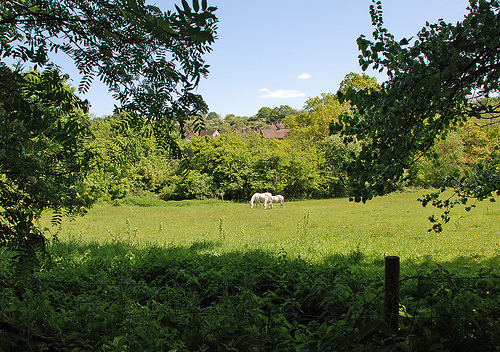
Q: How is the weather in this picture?
A: It is clear.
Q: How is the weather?
A: It is clear.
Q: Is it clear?
A: Yes, it is clear.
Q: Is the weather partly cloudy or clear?
A: It is clear.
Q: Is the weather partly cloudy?
A: No, it is clear.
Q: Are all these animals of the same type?
A: Yes, all the animals are horses.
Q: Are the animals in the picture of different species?
A: No, all the animals are horses.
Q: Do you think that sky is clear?
A: Yes, the sky is clear.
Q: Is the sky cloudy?
A: No, the sky is clear.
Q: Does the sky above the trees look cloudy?
A: No, the sky is clear.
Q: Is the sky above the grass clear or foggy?
A: The sky is clear.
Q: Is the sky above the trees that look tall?
A: Yes, the sky is above the trees.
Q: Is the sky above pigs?
A: No, the sky is above the horses.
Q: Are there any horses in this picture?
A: Yes, there is a horse.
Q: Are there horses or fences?
A: Yes, there is a horse.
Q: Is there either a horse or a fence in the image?
A: Yes, there is a horse.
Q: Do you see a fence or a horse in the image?
A: Yes, there is a horse.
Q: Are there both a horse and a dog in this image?
A: No, there is a horse but no dogs.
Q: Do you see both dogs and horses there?
A: No, there is a horse but no dogs.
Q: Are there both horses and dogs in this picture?
A: No, there is a horse but no dogs.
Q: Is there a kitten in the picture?
A: No, there are no kittens.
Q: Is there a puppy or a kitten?
A: No, there are no kittens or puppys.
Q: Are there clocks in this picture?
A: No, there are no clocks.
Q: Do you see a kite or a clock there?
A: No, there are no clocks or kites.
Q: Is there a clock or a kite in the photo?
A: No, there are no clocks or kites.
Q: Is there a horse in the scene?
A: Yes, there are horses.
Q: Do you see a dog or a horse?
A: Yes, there are horses.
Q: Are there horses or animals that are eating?
A: Yes, the horses are eating.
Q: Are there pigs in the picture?
A: No, there are no pigs.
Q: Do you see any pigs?
A: No, there are no pigs.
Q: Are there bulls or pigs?
A: No, there are no pigs or bulls.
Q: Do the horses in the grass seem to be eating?
A: Yes, the horses are eating.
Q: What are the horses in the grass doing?
A: The horses are eating.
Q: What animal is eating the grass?
A: The horses are eating the grass.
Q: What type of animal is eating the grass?
A: The animals are horses.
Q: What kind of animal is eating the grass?
A: The animals are horses.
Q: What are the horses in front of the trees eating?
A: The horses are eating grass.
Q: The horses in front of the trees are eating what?
A: The horses are eating grass.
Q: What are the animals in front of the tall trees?
A: The animals are horses.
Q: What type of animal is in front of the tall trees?
A: The animals are horses.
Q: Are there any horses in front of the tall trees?
A: Yes, there are horses in front of the trees.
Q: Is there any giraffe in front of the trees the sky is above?
A: No, there are horses in front of the trees.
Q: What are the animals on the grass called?
A: The animals are horses.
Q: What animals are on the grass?
A: The animals are horses.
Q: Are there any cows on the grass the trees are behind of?
A: No, there are horses on the grass.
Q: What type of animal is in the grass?
A: The animals are horses.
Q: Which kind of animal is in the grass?
A: The animals are horses.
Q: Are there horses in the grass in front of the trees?
A: Yes, there are horses in the grass.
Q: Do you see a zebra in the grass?
A: No, there are horses in the grass.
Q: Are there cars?
A: No, there are no cars.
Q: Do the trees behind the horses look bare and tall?
A: No, the trees are tall but leafy.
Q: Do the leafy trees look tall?
A: Yes, the trees are tall.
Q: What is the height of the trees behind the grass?
A: The trees are tall.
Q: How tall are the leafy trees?
A: The trees are tall.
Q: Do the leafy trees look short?
A: No, the trees are tall.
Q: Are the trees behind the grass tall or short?
A: The trees are tall.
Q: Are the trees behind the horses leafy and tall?
A: Yes, the trees are leafy and tall.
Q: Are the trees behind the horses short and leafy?
A: No, the trees are leafy but tall.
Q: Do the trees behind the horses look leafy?
A: Yes, the trees are leafy.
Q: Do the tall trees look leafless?
A: No, the trees are leafy.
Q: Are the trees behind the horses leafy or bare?
A: The trees are leafy.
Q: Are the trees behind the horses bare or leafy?
A: The trees are leafy.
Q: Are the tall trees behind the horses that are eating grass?
A: Yes, the trees are behind the horses.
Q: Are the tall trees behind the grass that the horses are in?
A: Yes, the trees are behind the grass.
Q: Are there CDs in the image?
A: No, there are no cds.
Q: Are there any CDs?
A: No, there are no cds.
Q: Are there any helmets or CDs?
A: No, there are no CDs or helmets.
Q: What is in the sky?
A: The clouds are in the sky.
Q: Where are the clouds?
A: The clouds are in the sky.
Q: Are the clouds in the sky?
A: Yes, the clouds are in the sky.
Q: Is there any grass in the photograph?
A: Yes, there is grass.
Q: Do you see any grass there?
A: Yes, there is grass.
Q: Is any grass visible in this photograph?
A: Yes, there is grass.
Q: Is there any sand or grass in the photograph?
A: Yes, there is grass.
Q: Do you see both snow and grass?
A: No, there is grass but no snow.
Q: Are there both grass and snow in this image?
A: No, there is grass but no snow.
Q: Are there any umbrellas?
A: No, there are no umbrellas.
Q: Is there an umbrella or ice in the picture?
A: No, there are no umbrellas or ice.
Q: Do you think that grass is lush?
A: Yes, the grass is lush.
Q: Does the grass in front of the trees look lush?
A: Yes, the grass is lush.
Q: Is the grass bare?
A: No, the grass is lush.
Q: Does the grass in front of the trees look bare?
A: No, the grass is lush.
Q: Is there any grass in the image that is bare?
A: No, there is grass but it is lush.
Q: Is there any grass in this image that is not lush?
A: No, there is grass but it is lush.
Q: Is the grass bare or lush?
A: The grass is lush.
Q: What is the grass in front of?
A: The grass is in front of the trees.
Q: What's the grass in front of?
A: The grass is in front of the trees.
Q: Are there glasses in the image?
A: No, there are no glasses.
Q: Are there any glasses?
A: No, there are no glasses.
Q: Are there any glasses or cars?
A: No, there are no glasses or cars.